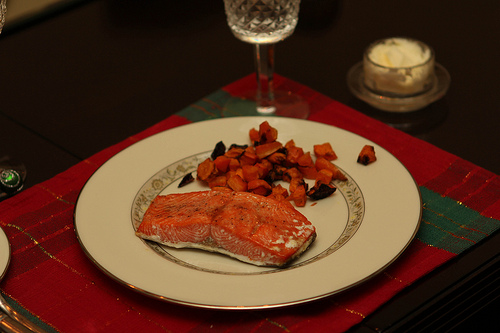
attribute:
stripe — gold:
[1, 221, 146, 316]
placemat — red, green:
[2, 69, 493, 324]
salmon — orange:
[136, 189, 316, 271]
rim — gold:
[72, 114, 422, 310]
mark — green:
[1, 170, 21, 189]